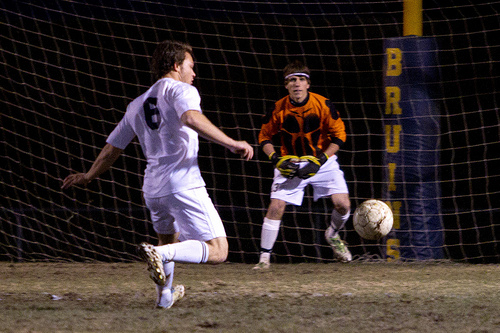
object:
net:
[0, 1, 492, 253]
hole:
[227, 206, 257, 240]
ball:
[351, 197, 396, 239]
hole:
[352, 164, 371, 184]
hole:
[416, 163, 439, 183]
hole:
[455, 207, 479, 231]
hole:
[32, 211, 46, 224]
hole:
[48, 201, 73, 221]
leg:
[244, 171, 299, 270]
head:
[286, 64, 312, 106]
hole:
[421, 196, 440, 213]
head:
[146, 35, 202, 83]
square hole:
[20, 122, 40, 142]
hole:
[352, 136, 367, 153]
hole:
[283, 238, 303, 256]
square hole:
[449, 156, 473, 182]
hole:
[235, 227, 248, 243]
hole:
[241, 251, 257, 265]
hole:
[312, 229, 327, 243]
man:
[251, 61, 351, 270]